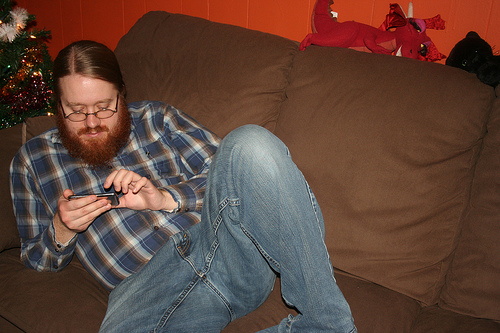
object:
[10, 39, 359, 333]
man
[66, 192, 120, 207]
cell phone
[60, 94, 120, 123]
glasses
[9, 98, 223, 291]
shirt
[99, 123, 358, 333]
jeans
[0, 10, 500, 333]
sofa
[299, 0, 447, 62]
toy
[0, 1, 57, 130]
tree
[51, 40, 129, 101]
hair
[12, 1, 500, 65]
wall